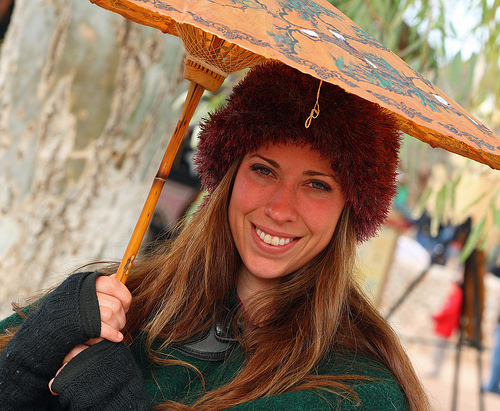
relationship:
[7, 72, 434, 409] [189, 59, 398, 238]
lady with hat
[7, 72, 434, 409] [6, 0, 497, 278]
lady with umbrella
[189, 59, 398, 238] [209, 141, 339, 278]
hat on head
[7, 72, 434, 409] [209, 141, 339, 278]
girl has face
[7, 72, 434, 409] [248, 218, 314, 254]
girl has smile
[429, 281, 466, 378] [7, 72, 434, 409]
person behind lady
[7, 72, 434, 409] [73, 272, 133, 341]
woman has hand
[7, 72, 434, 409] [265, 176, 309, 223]
woman has nose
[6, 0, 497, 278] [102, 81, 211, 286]
umbrella has pole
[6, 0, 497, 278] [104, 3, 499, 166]
umbrella has top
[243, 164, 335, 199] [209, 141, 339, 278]
eyes on face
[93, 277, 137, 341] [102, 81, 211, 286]
fingers around pole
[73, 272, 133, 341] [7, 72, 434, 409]
hand of woman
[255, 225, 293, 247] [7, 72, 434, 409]
teeth of woman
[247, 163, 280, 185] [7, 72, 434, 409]
eye of woman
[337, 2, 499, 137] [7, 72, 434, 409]
leaves behind woman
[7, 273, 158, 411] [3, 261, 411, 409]
sleeves on shirt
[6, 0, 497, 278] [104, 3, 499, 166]
umbrella with print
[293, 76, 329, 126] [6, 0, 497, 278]
string off of umbrella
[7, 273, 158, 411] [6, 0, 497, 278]
hands holding umbrella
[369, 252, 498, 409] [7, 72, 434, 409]
sidewalk behind woman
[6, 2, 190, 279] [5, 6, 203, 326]
bark on tree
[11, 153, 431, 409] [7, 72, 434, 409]
hair of woman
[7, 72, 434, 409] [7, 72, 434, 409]
hair of woman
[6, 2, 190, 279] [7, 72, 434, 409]
trunk behind woman